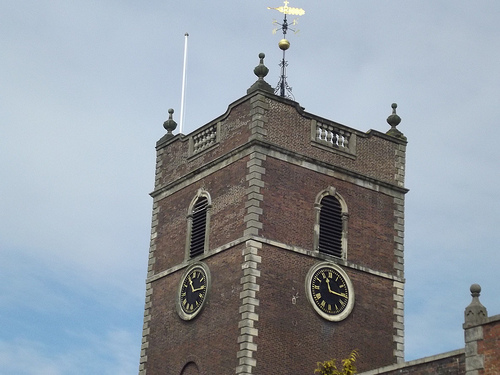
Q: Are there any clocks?
A: Yes, there is a clock.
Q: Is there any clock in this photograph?
A: Yes, there is a clock.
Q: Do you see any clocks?
A: Yes, there is a clock.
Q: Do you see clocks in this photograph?
A: Yes, there is a clock.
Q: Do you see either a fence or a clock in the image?
A: Yes, there is a clock.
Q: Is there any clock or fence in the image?
A: Yes, there is a clock.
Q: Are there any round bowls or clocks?
A: Yes, there is a round clock.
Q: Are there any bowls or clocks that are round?
A: Yes, the clock is round.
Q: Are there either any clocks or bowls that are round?
A: Yes, the clock is round.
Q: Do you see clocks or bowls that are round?
A: Yes, the clock is round.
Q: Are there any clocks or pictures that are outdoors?
A: Yes, the clock is outdoors.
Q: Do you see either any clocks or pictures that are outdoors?
A: Yes, the clock is outdoors.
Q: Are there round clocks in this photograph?
A: Yes, there is a round clock.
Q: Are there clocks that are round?
A: Yes, there is a clock that is round.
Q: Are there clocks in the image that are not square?
A: Yes, there is a round clock.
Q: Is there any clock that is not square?
A: Yes, there is a round clock.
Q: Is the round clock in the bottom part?
A: Yes, the clock is in the bottom of the image.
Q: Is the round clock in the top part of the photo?
A: No, the clock is in the bottom of the image.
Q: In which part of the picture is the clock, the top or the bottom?
A: The clock is in the bottom of the image.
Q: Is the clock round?
A: Yes, the clock is round.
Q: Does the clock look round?
A: Yes, the clock is round.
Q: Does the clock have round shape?
A: Yes, the clock is round.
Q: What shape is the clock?
A: The clock is round.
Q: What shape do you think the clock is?
A: The clock is round.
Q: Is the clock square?
A: No, the clock is round.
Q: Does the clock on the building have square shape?
A: No, the clock is round.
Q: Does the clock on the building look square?
A: No, the clock is round.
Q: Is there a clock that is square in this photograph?
A: No, there is a clock but it is round.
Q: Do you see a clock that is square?
A: No, there is a clock but it is round.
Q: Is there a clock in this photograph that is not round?
A: No, there is a clock but it is round.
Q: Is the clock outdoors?
A: Yes, the clock is outdoors.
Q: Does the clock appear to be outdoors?
A: Yes, the clock is outdoors.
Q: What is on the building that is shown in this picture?
A: The clock is on the building.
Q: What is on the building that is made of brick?
A: The clock is on the building.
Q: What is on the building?
A: The clock is on the building.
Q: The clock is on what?
A: The clock is on the building.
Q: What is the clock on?
A: The clock is on the building.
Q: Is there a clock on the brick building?
A: Yes, there is a clock on the building.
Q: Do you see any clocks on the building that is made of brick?
A: Yes, there is a clock on the building.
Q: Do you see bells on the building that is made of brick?
A: No, there is a clock on the building.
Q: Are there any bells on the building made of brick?
A: No, there is a clock on the building.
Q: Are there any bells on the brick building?
A: No, there is a clock on the building.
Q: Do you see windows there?
A: Yes, there is a window.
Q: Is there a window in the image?
A: Yes, there is a window.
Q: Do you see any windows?
A: Yes, there is a window.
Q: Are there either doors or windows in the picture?
A: Yes, there is a window.